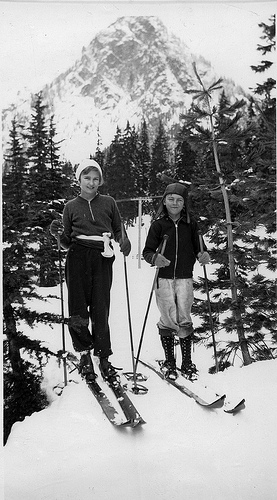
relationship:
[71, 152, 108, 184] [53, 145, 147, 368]
cap on head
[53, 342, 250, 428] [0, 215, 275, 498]
skis on snow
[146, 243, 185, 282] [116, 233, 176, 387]
hand holding ski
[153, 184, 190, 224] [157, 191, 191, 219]
black hat on head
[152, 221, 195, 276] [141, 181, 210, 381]
coat on boy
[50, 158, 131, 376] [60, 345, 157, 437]
boy on ski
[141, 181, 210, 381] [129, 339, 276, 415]
boy on ski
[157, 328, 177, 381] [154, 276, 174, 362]
boot on leg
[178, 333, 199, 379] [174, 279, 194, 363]
boot on leg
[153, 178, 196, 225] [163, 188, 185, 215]
black hat on head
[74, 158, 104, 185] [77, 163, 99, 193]
cap on head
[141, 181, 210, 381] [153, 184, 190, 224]
boy wearing black hat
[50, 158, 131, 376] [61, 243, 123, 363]
boy wearing pants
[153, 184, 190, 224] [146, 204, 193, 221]
black hat with ear flaps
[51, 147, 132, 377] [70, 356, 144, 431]
boy on skiis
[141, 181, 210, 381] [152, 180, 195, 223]
boy has cap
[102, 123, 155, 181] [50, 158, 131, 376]
trees behind boy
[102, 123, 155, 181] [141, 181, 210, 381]
trees behind boy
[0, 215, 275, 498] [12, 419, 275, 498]
snow on ground